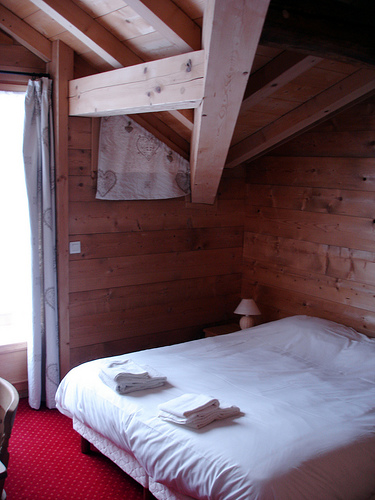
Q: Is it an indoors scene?
A: Yes, it is indoors.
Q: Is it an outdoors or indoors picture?
A: It is indoors.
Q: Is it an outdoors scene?
A: No, it is indoors.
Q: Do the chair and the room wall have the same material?
A: Yes, both the chair and the wall are made of wood.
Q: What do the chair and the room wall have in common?
A: The material, both the chair and the wall are wooden.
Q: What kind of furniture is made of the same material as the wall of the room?
A: The chair is made of the same material as the wall.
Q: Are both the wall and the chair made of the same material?
A: Yes, both the wall and the chair are made of wood.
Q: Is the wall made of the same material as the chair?
A: Yes, both the wall and the chair are made of wood.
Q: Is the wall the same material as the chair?
A: Yes, both the wall and the chair are made of wood.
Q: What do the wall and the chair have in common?
A: The material, both the wall and the chair are wooden.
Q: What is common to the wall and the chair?
A: The material, both the wall and the chair are wooden.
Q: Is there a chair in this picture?
A: Yes, there is a chair.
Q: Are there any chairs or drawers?
A: Yes, there is a chair.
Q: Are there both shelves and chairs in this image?
A: No, there is a chair but no shelves.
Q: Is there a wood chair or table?
A: Yes, there is a wood chair.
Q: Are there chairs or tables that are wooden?
A: Yes, the chair is wooden.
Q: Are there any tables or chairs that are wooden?
A: Yes, the chair is wooden.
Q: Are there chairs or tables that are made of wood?
A: Yes, the chair is made of wood.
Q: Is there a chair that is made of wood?
A: Yes, there is a chair that is made of wood.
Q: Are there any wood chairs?
A: Yes, there is a chair that is made of wood.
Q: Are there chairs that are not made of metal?
A: Yes, there is a chair that is made of wood.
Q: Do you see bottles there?
A: No, there are no bottles.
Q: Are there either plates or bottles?
A: No, there are no bottles or plates.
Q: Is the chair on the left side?
A: Yes, the chair is on the left of the image.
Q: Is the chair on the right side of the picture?
A: No, the chair is on the left of the image.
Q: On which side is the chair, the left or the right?
A: The chair is on the left of the image.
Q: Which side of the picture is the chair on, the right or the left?
A: The chair is on the left of the image.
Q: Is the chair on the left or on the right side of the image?
A: The chair is on the left of the image.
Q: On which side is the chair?
A: The chair is on the left of the image.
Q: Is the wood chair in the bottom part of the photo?
A: Yes, the chair is in the bottom of the image.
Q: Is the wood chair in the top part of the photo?
A: No, the chair is in the bottom of the image.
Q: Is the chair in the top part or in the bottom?
A: The chair is in the bottom of the image.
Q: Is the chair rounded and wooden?
A: Yes, the chair is rounded and wooden.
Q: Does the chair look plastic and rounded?
A: No, the chair is rounded but wooden.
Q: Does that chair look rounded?
A: Yes, the chair is rounded.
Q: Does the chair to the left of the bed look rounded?
A: Yes, the chair is rounded.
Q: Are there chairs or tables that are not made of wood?
A: No, there is a chair but it is made of wood.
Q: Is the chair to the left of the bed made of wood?
A: Yes, the chair is made of wood.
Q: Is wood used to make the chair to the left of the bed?
A: Yes, the chair is made of wood.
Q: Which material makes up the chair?
A: The chair is made of wood.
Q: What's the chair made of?
A: The chair is made of wood.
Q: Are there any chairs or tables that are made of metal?
A: No, there is a chair but it is made of wood.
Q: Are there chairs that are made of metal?
A: No, there is a chair but it is made of wood.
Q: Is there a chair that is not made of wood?
A: No, there is a chair but it is made of wood.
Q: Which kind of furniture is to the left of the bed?
A: The piece of furniture is a chair.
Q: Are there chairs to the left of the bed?
A: Yes, there is a chair to the left of the bed.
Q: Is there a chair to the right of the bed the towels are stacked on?
A: No, the chair is to the left of the bed.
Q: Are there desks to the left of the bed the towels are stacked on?
A: No, there is a chair to the left of the bed.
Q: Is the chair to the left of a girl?
A: No, the chair is to the left of the bed.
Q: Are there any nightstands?
A: Yes, there is a nightstand.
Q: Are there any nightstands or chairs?
A: Yes, there is a nightstand.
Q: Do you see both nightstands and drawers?
A: No, there is a nightstand but no drawers.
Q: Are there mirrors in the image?
A: No, there are no mirrors.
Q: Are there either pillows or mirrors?
A: No, there are no mirrors or pillows.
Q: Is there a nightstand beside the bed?
A: Yes, there is a nightstand beside the bed.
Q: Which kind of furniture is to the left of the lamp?
A: The piece of furniture is a nightstand.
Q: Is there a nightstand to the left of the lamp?
A: Yes, there is a nightstand to the left of the lamp.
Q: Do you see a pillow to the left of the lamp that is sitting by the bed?
A: No, there is a nightstand to the left of the lamp.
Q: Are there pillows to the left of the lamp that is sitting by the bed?
A: No, there is a nightstand to the left of the lamp.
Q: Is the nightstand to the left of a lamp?
A: Yes, the nightstand is to the left of a lamp.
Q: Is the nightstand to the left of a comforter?
A: No, the nightstand is to the left of a lamp.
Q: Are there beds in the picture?
A: Yes, there is a bed.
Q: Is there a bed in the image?
A: Yes, there is a bed.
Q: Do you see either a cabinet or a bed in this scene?
A: Yes, there is a bed.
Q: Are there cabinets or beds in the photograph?
A: Yes, there is a bed.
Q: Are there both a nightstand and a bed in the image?
A: Yes, there are both a bed and a nightstand.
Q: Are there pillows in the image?
A: No, there are no pillows.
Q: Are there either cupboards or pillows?
A: No, there are no pillows or cupboards.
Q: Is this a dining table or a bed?
A: This is a bed.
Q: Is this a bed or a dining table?
A: This is a bed.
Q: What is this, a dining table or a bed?
A: This is a bed.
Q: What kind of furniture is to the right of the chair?
A: The piece of furniture is a bed.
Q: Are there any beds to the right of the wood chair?
A: Yes, there is a bed to the right of the chair.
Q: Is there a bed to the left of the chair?
A: No, the bed is to the right of the chair.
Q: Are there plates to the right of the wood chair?
A: No, there is a bed to the right of the chair.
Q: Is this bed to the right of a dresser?
A: No, the bed is to the right of the chair.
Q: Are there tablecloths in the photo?
A: No, there are no tablecloths.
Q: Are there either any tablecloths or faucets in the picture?
A: No, there are no tablecloths or faucets.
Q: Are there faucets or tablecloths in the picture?
A: No, there are no tablecloths or faucets.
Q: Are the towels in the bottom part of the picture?
A: Yes, the towels are in the bottom of the image.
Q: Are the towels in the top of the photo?
A: No, the towels are in the bottom of the image.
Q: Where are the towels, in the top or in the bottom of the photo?
A: The towels are in the bottom of the image.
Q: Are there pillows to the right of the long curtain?
A: No, there are towels to the right of the curtain.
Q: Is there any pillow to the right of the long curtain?
A: No, there are towels to the right of the curtain.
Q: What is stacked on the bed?
A: The towels are stacked on the bed.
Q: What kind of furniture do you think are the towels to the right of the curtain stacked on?
A: The towels are stacked on the bed.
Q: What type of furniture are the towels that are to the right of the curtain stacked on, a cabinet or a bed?
A: The towels are stacked on a bed.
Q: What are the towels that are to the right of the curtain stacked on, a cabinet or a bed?
A: The towels are stacked on a bed.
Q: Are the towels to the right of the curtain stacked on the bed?
A: Yes, the towels are stacked on the bed.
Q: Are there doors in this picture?
A: Yes, there is a door.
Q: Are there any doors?
A: Yes, there is a door.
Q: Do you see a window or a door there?
A: Yes, there is a door.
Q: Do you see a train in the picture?
A: No, there are no trains.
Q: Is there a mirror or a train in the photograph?
A: No, there are no trains or mirrors.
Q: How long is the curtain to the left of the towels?
A: The curtain is long.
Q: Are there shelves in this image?
A: No, there are no shelves.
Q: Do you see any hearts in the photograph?
A: Yes, there is a heart.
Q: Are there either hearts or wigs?
A: Yes, there is a heart.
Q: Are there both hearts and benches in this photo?
A: No, there is a heart but no benches.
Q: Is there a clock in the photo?
A: No, there are no clocks.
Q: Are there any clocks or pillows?
A: No, there are no clocks or pillows.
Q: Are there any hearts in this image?
A: Yes, there is a heart.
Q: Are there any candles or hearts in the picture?
A: Yes, there is a heart.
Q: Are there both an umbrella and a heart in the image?
A: No, there is a heart but no umbrellas.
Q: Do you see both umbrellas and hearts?
A: No, there is a heart but no umbrellas.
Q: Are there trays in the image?
A: No, there are no trays.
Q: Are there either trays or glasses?
A: No, there are no trays or glasses.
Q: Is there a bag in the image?
A: No, there are no bags.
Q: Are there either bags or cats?
A: No, there are no bags or cats.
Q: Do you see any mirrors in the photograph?
A: No, there are no mirrors.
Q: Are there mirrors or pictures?
A: No, there are no mirrors or pictures.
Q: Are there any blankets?
A: No, there are no blankets.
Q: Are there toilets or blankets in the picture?
A: No, there are no blankets or toilets.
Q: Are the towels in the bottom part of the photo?
A: Yes, the towels are in the bottom of the image.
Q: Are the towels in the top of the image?
A: No, the towels are in the bottom of the image.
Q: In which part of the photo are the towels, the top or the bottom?
A: The towels are in the bottom of the image.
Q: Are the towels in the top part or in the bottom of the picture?
A: The towels are in the bottom of the image.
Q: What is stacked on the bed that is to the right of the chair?
A: The towels are stacked on the bed.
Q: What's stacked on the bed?
A: The towels are stacked on the bed.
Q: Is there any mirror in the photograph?
A: No, there are no mirrors.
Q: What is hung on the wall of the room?
A: The curtain is hung on the wall.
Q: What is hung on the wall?
A: The curtain is hung on the wall.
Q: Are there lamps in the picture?
A: Yes, there is a lamp.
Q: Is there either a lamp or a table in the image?
A: Yes, there is a lamp.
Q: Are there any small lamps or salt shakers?
A: Yes, there is a small lamp.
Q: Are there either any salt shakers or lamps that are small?
A: Yes, the lamp is small.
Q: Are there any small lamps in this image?
A: Yes, there is a small lamp.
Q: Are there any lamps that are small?
A: Yes, there is a lamp that is small.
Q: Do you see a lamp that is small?
A: Yes, there is a lamp that is small.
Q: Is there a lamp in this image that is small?
A: Yes, there is a lamp that is small.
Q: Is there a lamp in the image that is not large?
A: Yes, there is a small lamp.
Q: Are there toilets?
A: No, there are no toilets.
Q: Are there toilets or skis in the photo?
A: No, there are no toilets or skis.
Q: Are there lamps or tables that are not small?
A: No, there is a lamp but it is small.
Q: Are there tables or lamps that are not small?
A: No, there is a lamp but it is small.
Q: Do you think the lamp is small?
A: Yes, the lamp is small.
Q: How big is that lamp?
A: The lamp is small.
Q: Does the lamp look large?
A: No, the lamp is small.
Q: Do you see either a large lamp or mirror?
A: No, there is a lamp but it is small.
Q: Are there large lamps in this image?
A: No, there is a lamp but it is small.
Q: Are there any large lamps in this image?
A: No, there is a lamp but it is small.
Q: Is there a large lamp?
A: No, there is a lamp but it is small.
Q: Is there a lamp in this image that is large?
A: No, there is a lamp but it is small.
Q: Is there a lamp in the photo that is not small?
A: No, there is a lamp but it is small.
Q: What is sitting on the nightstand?
A: The lamp is sitting on the nightstand.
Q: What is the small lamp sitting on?
A: The lamp is sitting on the nightstand.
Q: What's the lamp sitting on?
A: The lamp is sitting on the nightstand.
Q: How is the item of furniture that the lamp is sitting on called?
A: The piece of furniture is a nightstand.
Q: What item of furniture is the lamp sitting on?
A: The lamp is sitting on the nightstand.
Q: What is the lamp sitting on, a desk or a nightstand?
A: The lamp is sitting on a nightstand.